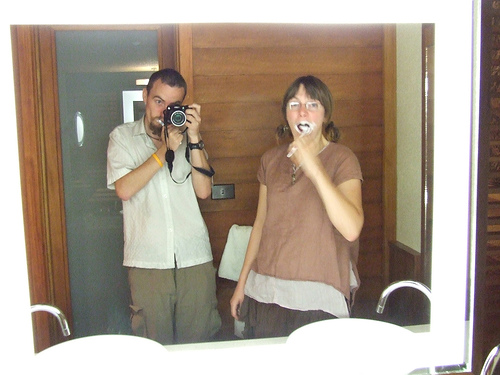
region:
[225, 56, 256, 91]
dark brown wood on wall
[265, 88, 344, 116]
clear glasses on woman's face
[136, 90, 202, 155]
camera in man's hand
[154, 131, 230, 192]
black straps on camera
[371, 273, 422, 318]
long curved silver faucet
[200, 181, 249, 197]
black and silver thermometer on wall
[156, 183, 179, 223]
white buttons on shirt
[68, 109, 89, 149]
small white light on the wall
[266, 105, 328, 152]
toothbrush in woman's mouth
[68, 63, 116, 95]
gray paint on the wall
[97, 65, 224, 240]
man taking a picture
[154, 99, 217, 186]
the camera is black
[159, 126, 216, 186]
straps around arms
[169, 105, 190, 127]
lens of camera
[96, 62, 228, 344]
man wears a white shirt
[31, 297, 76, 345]
the faucet is color silver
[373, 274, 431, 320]
the faucet is color silver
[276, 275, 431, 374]
a sink on right side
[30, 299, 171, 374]
a sink on left side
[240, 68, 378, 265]
woman brushing her teeth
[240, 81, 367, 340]
Lady wearing a brown shirt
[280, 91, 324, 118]
Eyeglasses on the woman's face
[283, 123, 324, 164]
Toothbrush in the woman's hand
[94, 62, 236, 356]
Man wearing a white shirt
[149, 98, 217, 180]
Camera in the man's hands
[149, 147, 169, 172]
Wristband on the man's arm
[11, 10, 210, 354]
Door behind the man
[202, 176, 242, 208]
switch on the wall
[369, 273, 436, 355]
Faucet over the sink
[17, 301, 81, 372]
Faucet over the sink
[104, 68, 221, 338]
man holding camera taking photo in mirror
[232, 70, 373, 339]
girl brushing teethe wearing glasses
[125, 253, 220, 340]
khaki shorts on man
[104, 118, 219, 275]
man wearing short sleeve white shirt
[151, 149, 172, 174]
yellow bracelet on man's right wrist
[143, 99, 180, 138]
beard on man's face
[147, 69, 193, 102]
short dark hair on man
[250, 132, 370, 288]
brown short sleeved shirt on girl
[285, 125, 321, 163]
toothbrush in girl's mouth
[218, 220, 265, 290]
white towel in background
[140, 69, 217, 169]
reflection of man with camera in mirror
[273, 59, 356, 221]
woman brushing teeth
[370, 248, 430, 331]
silver sink faucet in mirror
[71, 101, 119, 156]
reflection of light in mirror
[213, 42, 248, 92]
brown wooden tile behind woman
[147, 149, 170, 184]
orange rubber bracelet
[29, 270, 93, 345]
silver faucet reflected in mirror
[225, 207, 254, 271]
white towel behind woman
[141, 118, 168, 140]
brown beird on man in photo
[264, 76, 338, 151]
the head of a woman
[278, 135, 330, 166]
the hand of a woman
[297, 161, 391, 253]
the arm of a woman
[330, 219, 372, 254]
the elbow of a woman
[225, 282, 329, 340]
the pants of a woman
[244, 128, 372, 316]
the shirt of a woman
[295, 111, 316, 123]
the nose of a woman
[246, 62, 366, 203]
A woman is brushing her teeth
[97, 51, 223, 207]
A man is holding a camera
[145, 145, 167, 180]
A yellow bracelet around a wrist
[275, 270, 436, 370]
A faucet over a white sink